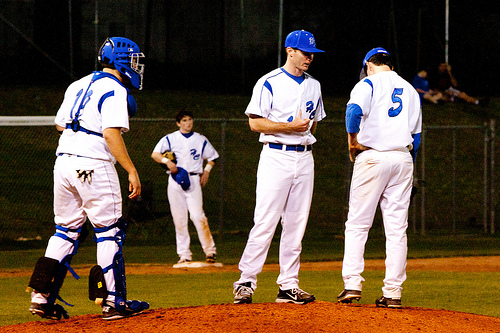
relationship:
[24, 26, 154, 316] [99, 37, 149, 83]
catcher wears helmet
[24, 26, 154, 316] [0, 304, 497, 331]
catcher on pitcher mound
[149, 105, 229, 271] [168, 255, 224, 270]
player on base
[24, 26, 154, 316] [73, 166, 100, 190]
catcher has catcher's pocket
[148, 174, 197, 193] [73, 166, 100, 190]
glove in catcher's pocket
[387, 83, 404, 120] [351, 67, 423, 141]
5 on jersey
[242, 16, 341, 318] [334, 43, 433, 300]
pitcher talking to teammate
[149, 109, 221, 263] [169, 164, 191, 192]
waiting man with held hat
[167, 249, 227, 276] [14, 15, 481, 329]
base plate for baseball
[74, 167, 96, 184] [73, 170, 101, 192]
gloves in a catcher's pocket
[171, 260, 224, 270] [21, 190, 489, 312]
base on field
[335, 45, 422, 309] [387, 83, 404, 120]
player wearing 5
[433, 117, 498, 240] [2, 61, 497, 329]
metal fence behind baseball field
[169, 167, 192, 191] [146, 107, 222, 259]
blue cap held by player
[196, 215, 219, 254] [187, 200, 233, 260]
dirt spot on leg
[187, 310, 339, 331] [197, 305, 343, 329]
dirt used to form mound